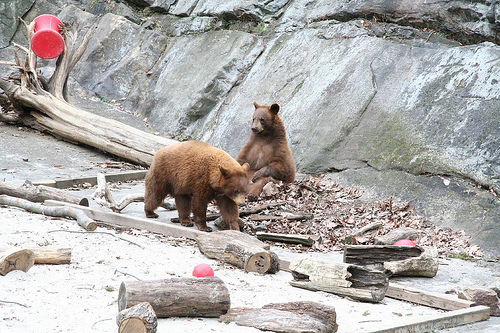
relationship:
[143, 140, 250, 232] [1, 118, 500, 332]
bear on ground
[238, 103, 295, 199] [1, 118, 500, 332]
bear on ground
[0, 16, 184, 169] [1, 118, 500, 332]
log on ground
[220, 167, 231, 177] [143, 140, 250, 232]
ear of a bear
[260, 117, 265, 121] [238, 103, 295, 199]
eye of bear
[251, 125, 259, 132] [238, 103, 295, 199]
nose of bear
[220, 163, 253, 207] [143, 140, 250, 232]
head of bear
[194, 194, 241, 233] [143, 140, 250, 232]
front legs of bear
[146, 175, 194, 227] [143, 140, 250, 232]
back legs of bear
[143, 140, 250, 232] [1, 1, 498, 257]
bear beside wall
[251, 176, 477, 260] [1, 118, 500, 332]
leaves on ground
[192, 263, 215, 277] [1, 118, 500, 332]
ball on ground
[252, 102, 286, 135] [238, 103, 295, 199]
head of bear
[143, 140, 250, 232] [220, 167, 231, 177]
bear has an ear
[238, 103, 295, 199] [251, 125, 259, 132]
bear has a nose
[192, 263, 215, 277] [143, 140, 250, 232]
ball near bear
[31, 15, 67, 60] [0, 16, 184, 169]
basket in log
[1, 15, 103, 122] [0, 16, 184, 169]
branches on log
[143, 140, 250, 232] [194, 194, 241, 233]
bear has front legs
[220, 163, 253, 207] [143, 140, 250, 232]
head of a bear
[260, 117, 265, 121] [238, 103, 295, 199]
eye of a bear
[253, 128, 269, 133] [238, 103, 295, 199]
mouth of a bear